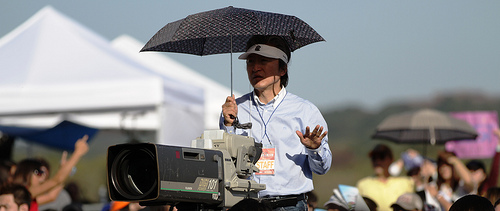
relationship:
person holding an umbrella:
[220, 37, 332, 210] [138, 6, 327, 124]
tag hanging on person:
[250, 83, 288, 174] [220, 37, 332, 210]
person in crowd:
[353, 144, 416, 210] [353, 142, 499, 210]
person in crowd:
[445, 125, 499, 193] [353, 142, 499, 210]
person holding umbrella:
[220, 37, 332, 210] [138, 6, 327, 124]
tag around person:
[250, 83, 288, 174] [220, 37, 332, 210]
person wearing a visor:
[220, 37, 332, 210] [238, 43, 291, 66]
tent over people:
[0, 6, 249, 151] [2, 135, 96, 210]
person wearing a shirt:
[220, 37, 332, 210] [219, 87, 332, 197]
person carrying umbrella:
[220, 37, 332, 210] [138, 6, 327, 124]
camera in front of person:
[108, 129, 266, 210] [220, 37, 332, 210]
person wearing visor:
[220, 37, 332, 210] [238, 43, 291, 66]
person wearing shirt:
[220, 37, 332, 210] [219, 87, 332, 197]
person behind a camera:
[220, 37, 332, 210] [108, 129, 266, 210]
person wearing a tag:
[220, 37, 332, 210] [250, 83, 288, 174]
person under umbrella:
[353, 144, 416, 210] [369, 107, 479, 162]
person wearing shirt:
[353, 144, 416, 210] [357, 175, 414, 210]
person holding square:
[445, 125, 499, 193] [441, 110, 500, 158]